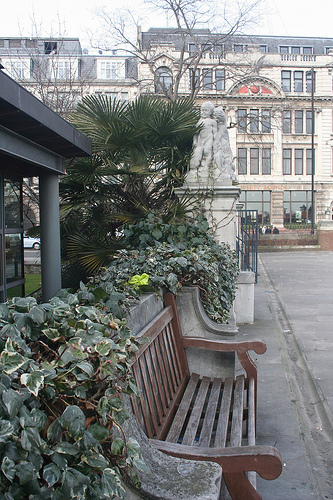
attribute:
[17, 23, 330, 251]
window — glass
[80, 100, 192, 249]
plant — palm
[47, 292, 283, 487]
bench — wooden, brown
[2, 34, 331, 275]
building — beige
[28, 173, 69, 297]
pillar — concrete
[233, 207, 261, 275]
fencing — metal, black, iron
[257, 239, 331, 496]
sidewalk — grey, bare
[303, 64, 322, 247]
pole — metal, black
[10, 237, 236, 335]
planter — gray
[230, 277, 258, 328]
wall — white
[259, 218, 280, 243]
people — distant, standing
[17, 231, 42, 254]
car — white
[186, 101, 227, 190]
statue — standing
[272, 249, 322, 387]
street — gray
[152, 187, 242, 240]
tree — bare